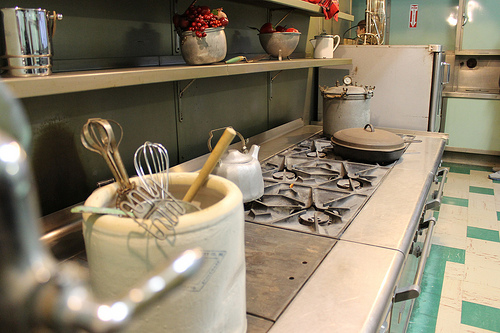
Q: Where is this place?
A: The kitchen.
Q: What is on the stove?
A: A teapot.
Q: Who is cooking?
A: Nobody.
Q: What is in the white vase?
A: Cake mixers.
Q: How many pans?
A: One.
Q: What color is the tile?
A: White and green.